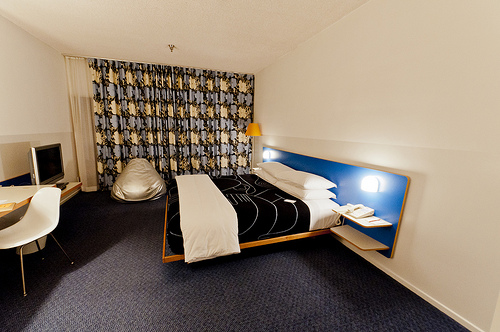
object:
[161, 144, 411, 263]
bed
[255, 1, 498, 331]
wall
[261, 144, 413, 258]
headboard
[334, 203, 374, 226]
phone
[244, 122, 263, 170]
lamp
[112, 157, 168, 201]
bean bag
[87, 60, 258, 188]
curtain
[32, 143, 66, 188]
television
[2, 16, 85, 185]
wall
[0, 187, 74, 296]
chair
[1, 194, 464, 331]
carpet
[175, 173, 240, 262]
blanket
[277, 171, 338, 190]
pillows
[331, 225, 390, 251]
shelves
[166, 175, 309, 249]
comforter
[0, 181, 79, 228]
desk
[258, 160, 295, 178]
pillows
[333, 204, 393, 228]
shelf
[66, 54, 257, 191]
window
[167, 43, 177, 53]
sprinkler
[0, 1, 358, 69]
ceiling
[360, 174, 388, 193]
light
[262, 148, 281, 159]
light